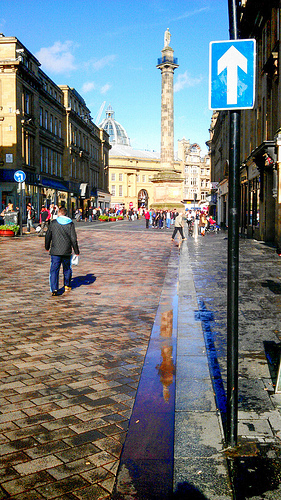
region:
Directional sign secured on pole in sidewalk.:
[209, 40, 254, 450]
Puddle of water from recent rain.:
[121, 296, 179, 491]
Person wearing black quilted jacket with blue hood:
[43, 215, 80, 254]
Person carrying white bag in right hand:
[68, 253, 81, 266]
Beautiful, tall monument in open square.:
[149, 26, 184, 219]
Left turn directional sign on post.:
[13, 170, 25, 236]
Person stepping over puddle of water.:
[172, 211, 184, 241]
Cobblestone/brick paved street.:
[1, 228, 174, 498]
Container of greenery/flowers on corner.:
[1, 225, 17, 236]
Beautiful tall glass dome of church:
[96, 103, 132, 148]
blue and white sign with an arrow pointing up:
[208, 37, 254, 109]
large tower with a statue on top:
[150, 26, 182, 213]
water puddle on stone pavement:
[128, 295, 205, 488]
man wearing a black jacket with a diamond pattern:
[44, 205, 80, 257]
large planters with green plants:
[0, 210, 125, 238]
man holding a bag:
[52, 207, 80, 268]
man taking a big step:
[169, 210, 188, 243]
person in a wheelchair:
[206, 213, 223, 234]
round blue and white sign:
[13, 167, 27, 182]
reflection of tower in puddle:
[151, 27, 188, 405]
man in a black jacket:
[44, 201, 76, 296]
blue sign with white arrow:
[206, 38, 260, 109]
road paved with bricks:
[3, 226, 173, 498]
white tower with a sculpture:
[155, 23, 183, 208]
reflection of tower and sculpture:
[153, 299, 183, 408]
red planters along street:
[0, 220, 22, 235]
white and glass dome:
[94, 99, 130, 145]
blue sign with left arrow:
[12, 166, 30, 180]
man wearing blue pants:
[38, 203, 76, 294]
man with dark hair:
[45, 204, 83, 301]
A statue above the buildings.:
[151, 20, 179, 56]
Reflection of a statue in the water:
[151, 297, 200, 407]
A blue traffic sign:
[13, 166, 26, 192]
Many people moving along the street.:
[137, 204, 210, 233]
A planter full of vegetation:
[3, 221, 53, 240]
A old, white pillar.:
[155, 74, 178, 151]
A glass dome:
[108, 110, 124, 138]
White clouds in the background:
[47, 40, 77, 68]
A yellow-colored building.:
[110, 158, 150, 205]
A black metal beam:
[219, 268, 236, 438]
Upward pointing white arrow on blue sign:
[208, 40, 253, 109]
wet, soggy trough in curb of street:
[157, 243, 218, 498]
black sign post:
[232, 109, 239, 367]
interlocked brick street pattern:
[1, 288, 127, 422]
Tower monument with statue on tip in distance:
[157, 25, 182, 216]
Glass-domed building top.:
[99, 101, 130, 145]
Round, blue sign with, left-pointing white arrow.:
[13, 169, 25, 183]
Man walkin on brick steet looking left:
[45, 206, 81, 295]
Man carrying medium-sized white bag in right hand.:
[43, 206, 79, 295]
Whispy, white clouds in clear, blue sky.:
[38, 35, 148, 70]